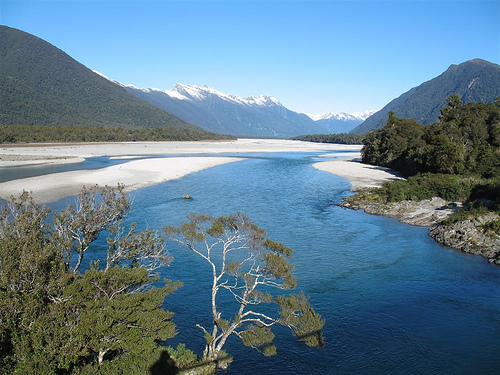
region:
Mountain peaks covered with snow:
[93, 64, 385, 141]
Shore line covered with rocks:
[374, 195, 499, 263]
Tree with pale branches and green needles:
[8, 188, 330, 373]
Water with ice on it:
[5, 138, 496, 371]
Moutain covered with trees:
[2, 22, 241, 142]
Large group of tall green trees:
[358, 98, 498, 178]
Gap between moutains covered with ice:
[230, 126, 299, 147]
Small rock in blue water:
[172, 188, 201, 202]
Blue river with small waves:
[4, 141, 498, 369]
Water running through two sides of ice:
[2, 155, 177, 180]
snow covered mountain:
[91, 68, 374, 141]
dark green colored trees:
[360, 93, 499, 206]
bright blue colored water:
[0, 146, 498, 373]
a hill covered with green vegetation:
[0, 27, 238, 141]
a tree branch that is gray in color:
[163, 212, 326, 362]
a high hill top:
[348, 56, 498, 135]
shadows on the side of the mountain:
[126, 91, 371, 139]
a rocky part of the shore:
[343, 185, 499, 260]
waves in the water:
[308, 190, 415, 292]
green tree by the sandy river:
[165, 212, 315, 370]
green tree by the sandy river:
[80, 222, 172, 370]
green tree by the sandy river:
[0, 176, 131, 372]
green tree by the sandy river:
[365, 132, 380, 165]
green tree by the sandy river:
[440, 131, 465, 177]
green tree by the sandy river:
[385, 110, 396, 126]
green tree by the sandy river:
[397, 116, 427, 153]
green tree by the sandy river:
[442, 90, 462, 128]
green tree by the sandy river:
[471, 113, 488, 148]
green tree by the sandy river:
[487, 114, 498, 151]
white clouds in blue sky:
[69, 14, 126, 31]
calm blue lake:
[226, 158, 320, 222]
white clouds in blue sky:
[337, 22, 389, 56]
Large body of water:
[363, 254, 461, 346]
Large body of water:
[255, 173, 312, 208]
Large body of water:
[349, 295, 437, 369]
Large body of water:
[384, 293, 498, 373]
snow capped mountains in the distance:
[82, 67, 377, 142]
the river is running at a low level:
[1, 134, 498, 374]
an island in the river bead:
[0, 151, 246, 213]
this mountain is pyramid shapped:
[346, 55, 499, 146]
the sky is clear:
[0, 1, 499, 118]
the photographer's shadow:
[146, 343, 178, 373]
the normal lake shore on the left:
[1, 130, 244, 153]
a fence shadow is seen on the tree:
[177, 325, 327, 371]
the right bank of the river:
[315, 143, 497, 268]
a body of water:
[45, 103, 468, 367]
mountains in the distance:
[132, 68, 352, 138]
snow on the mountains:
[139, 77, 309, 112]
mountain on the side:
[0, 15, 202, 154]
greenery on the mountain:
[3, 23, 185, 134]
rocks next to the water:
[371, 190, 498, 252]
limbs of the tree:
[180, 242, 253, 342]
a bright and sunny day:
[8, 9, 490, 356]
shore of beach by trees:
[311, 151, 401, 198]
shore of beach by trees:
[303, 152, 413, 199]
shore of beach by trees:
[307, 142, 419, 202]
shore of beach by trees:
[307, 147, 414, 214]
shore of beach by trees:
[313, 145, 412, 207]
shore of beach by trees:
[310, 146, 405, 207]